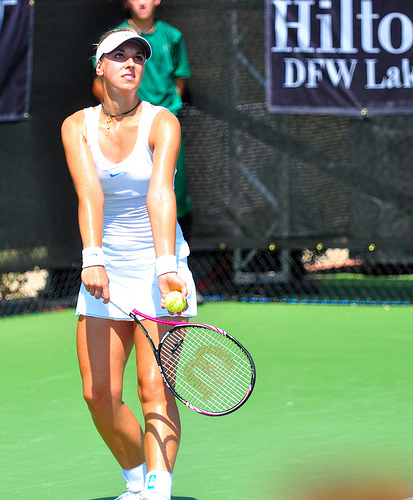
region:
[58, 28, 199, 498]
woman playing tennis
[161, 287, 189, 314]
ball in womans hand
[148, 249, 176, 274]
womans left arm band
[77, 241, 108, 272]
womans white arm band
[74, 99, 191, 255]
womans white tank top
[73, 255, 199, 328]
womans white skort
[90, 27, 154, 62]
sun visor the woman is wearing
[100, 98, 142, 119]
choker necklace the woman is wearing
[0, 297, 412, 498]
green tennis court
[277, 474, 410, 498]
photographers finger in front of lens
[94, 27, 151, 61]
girl wearing visor for protection against sun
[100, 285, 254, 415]
raising tennis racket to serve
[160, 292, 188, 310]
ball in hand getting ready to throw up in air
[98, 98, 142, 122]
wearing pendant around neck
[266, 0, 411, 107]
large advertisment sign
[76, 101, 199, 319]
wearing white tennis outfit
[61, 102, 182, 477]
skin glistening with sweat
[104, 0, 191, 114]
man standing in the background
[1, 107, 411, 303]
fence in the background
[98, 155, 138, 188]
wearing nike logo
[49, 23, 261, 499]
woman preparing to serve tennis ball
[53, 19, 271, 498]
tennis player holding tennis racket and tennis ball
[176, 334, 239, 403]
sport brand logo on mesh of tennis racket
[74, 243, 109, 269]
white wrist band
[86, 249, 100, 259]
dark nike logo on white wristband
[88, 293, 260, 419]
pink and black tennis racket with white handle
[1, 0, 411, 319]
tall chain link metal fence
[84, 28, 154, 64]
white visor on woman's head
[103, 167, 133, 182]
nike logo on front of white tank top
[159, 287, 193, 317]
green tennis ball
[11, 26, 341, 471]
woman playing tennis on court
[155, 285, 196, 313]
yellow tennis ball in hand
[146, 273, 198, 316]
hand holding yellow tennis ball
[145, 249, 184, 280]
white wrist band on woman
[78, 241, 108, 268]
white wrist band on woman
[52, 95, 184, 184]
sweat glistening on woman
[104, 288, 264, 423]
pink and black tennis racket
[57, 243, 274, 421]
hand holding tennis racket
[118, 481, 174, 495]
tops of white tennis shoes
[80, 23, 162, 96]
white tennis visor on head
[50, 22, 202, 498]
Women playing tennis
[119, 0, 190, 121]
boy in background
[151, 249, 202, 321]
tennis ball in hand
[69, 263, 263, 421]
Tennis racket in hand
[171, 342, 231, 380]
strings on tennis racket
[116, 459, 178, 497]
white tennis socks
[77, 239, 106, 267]
white sweat band on tennis player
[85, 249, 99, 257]
company logo on white sweatband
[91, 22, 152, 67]
hat on tennis players head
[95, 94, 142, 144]
necklace on tennis player